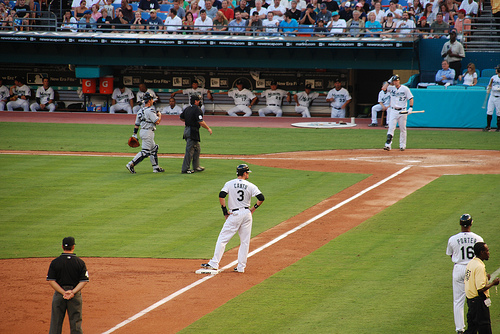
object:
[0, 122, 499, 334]
grass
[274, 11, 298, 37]
people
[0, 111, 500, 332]
ground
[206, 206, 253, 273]
trouser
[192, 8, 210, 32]
people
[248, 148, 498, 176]
sand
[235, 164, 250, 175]
helmet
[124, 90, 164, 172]
baseball player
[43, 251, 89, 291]
t shirt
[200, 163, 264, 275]
player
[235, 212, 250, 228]
white